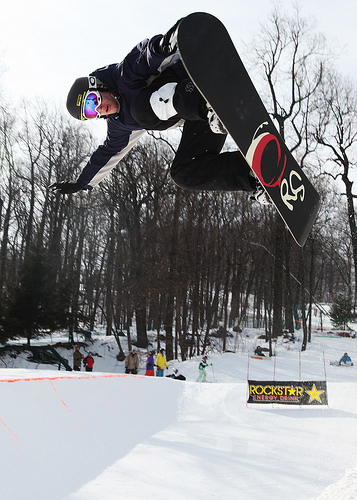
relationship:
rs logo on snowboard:
[279, 171, 306, 213] [170, 7, 325, 249]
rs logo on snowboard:
[233, 119, 314, 225] [170, 7, 325, 249]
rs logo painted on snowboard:
[279, 171, 306, 213] [170, 7, 325, 249]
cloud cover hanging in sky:
[2, 1, 344, 278] [2, 1, 346, 270]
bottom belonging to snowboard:
[175, 10, 323, 248] [170, 7, 325, 249]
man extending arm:
[46, 16, 272, 206] [46, 120, 147, 195]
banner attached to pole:
[246, 379, 328, 406] [272, 349, 276, 408]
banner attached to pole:
[246, 379, 328, 406] [298, 349, 303, 408]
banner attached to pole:
[246, 379, 328, 406] [244, 349, 249, 408]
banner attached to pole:
[246, 379, 328, 406] [321, 350, 329, 407]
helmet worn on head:
[64, 75, 107, 121] [63, 75, 120, 120]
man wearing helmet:
[46, 17, 272, 206] [64, 75, 107, 121]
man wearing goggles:
[46, 17, 272, 206] [59, 74, 103, 134]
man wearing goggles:
[46, 17, 272, 206] [68, 56, 113, 131]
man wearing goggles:
[46, 17, 272, 206] [62, 68, 108, 140]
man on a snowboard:
[46, 17, 272, 206] [163, 2, 332, 256]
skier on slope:
[83, 348, 95, 371] [6, 365, 243, 487]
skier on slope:
[335, 348, 351, 364] [305, 331, 355, 403]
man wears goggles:
[46, 17, 272, 206] [81, 84, 103, 122]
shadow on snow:
[162, 430, 269, 477] [0, 381, 355, 498]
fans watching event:
[70, 344, 214, 382] [246, 381, 329, 407]